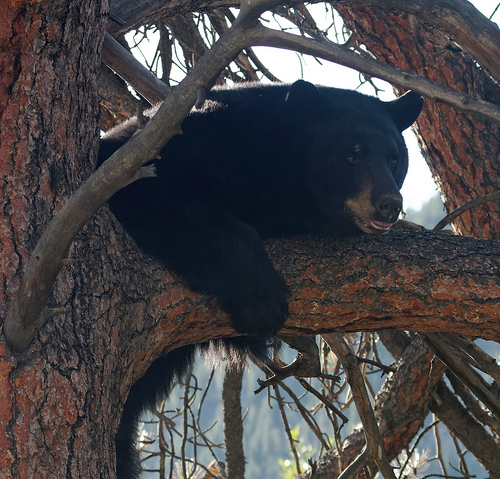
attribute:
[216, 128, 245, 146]
fur — black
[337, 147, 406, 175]
eyes — small, black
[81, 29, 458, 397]
bear — black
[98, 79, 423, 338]
bear — black, resting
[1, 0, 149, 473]
tree — large, brown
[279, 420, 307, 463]
leaves — green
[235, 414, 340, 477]
flowers — white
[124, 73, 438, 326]
bear — black, climbing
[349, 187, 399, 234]
mouth — brown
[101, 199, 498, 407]
branch — thick